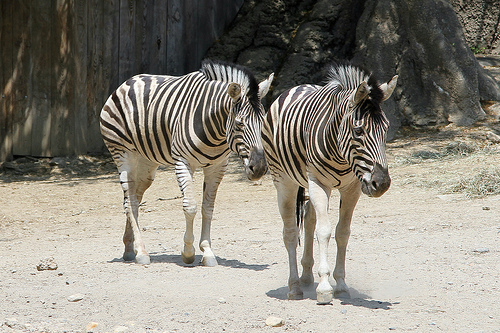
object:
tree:
[272, 6, 500, 137]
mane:
[204, 63, 260, 111]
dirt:
[0, 179, 114, 332]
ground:
[0, 127, 499, 333]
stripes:
[125, 78, 149, 159]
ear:
[377, 75, 398, 101]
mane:
[326, 65, 383, 116]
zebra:
[261, 65, 398, 305]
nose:
[370, 167, 391, 198]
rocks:
[37, 256, 57, 271]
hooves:
[316, 290, 333, 303]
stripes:
[193, 80, 226, 148]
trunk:
[284, 0, 497, 129]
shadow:
[105, 253, 267, 270]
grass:
[439, 159, 500, 195]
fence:
[0, 0, 185, 157]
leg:
[336, 187, 362, 277]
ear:
[348, 82, 367, 109]